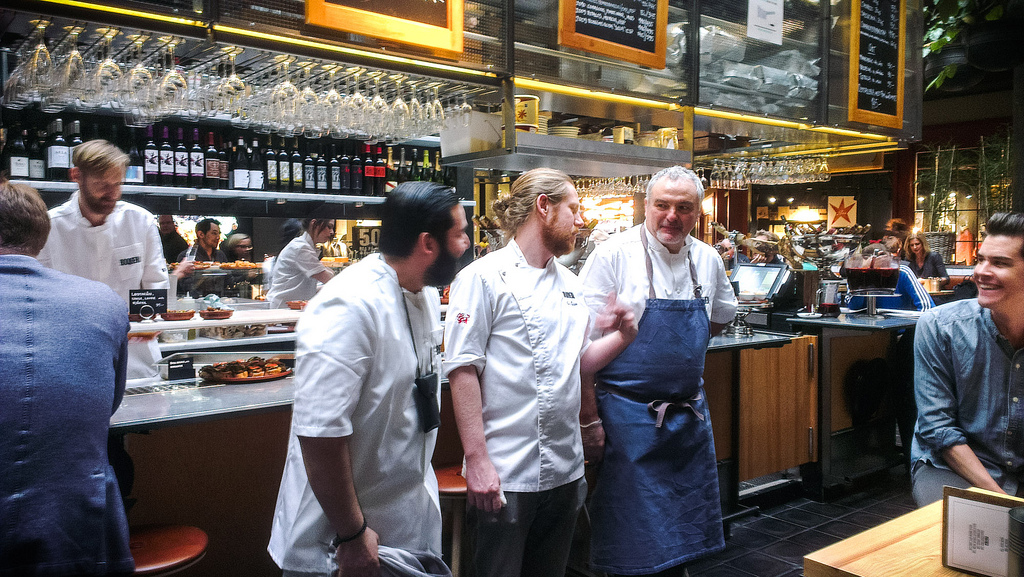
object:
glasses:
[0, 19, 473, 146]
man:
[911, 212, 1023, 508]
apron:
[566, 225, 727, 575]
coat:
[440, 237, 598, 492]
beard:
[422, 231, 469, 287]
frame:
[558, 0, 668, 70]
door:
[739, 335, 818, 482]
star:
[827, 196, 854, 228]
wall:
[751, 172, 894, 244]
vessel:
[186, 245, 199, 261]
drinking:
[143, 125, 204, 187]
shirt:
[911, 298, 1024, 496]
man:
[0, 183, 139, 577]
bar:
[107, 289, 307, 429]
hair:
[380, 181, 462, 264]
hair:
[492, 167, 575, 246]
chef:
[36, 140, 171, 315]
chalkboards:
[848, 0, 908, 130]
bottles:
[0, 118, 458, 197]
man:
[266, 181, 472, 576]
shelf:
[0, 180, 477, 206]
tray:
[198, 370, 293, 381]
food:
[198, 356, 293, 381]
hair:
[644, 165, 705, 219]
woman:
[904, 234, 951, 291]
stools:
[129, 527, 208, 577]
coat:
[0, 254, 137, 577]